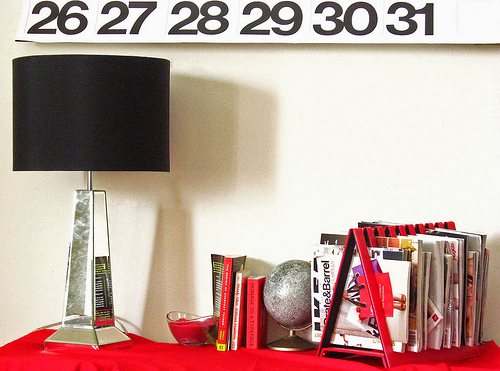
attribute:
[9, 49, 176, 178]
blackshade — black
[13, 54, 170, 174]
lampshade — black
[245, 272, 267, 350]
book — red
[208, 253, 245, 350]
book — red, standing up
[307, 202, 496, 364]
rack — triangle shaped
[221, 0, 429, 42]
numbers — black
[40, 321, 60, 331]
cord — lamps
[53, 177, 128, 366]
base — clear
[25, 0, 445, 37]
numbers — 26  , 31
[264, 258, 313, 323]
sphere — silver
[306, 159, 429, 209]
wall — blank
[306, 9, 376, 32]
number — black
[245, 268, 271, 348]
book — standing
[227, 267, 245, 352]
book — standing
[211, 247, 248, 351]
book — standing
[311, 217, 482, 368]
magazine rack — red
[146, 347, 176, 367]
cloth — red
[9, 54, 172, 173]
shade — black, lamp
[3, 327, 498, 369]
material — red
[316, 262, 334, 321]
writing — black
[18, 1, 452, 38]
background — white